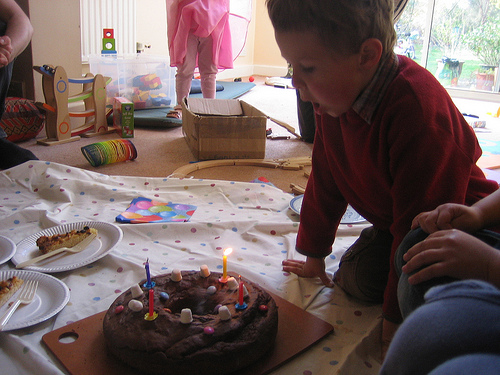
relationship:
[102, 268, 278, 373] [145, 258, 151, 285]
cake with candlei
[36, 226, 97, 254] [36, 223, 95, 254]
pie of pie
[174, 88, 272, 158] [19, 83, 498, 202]
box on floor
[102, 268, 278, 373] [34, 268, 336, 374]
cake on top of plate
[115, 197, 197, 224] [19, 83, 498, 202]
napkin are on top of floor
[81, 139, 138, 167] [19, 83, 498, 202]
toy are on top of floor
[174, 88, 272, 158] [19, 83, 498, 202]
box lying on floor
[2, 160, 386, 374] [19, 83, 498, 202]
cloth lying on floor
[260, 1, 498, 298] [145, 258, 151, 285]
boy blowing candlei